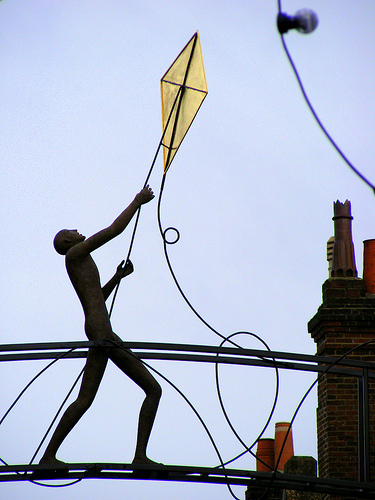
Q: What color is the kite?
A: Yellow.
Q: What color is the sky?
A: Blue.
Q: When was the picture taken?
A: Daytime.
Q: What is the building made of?
A: Brick.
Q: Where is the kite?
A: In the sky.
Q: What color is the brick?
A: Red.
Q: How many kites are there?
A: One.